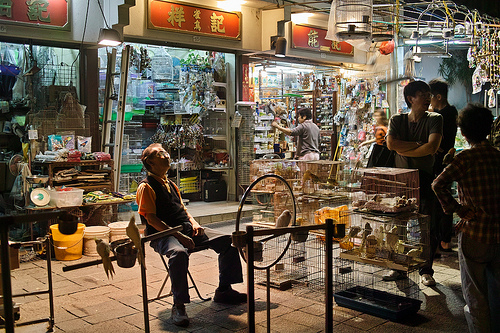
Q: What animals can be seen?
A: Birds.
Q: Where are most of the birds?
A: In cages.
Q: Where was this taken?
A: At a market.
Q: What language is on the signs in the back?
A: Chinese.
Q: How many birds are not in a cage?
A: Three.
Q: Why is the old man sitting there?
A: He is selling the birds.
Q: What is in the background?
A: Shops.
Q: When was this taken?
A: At night.